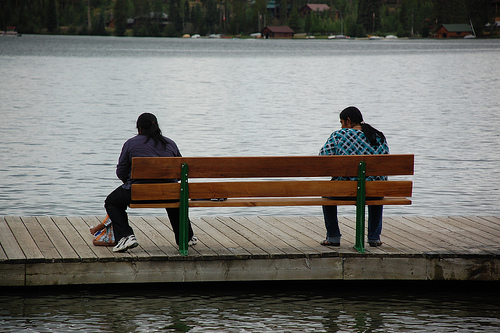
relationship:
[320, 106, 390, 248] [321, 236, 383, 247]
woman in sandals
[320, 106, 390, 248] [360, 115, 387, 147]
woman has pony tail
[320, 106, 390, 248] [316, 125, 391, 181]
woman in striped shirt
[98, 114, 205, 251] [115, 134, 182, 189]
person in shirt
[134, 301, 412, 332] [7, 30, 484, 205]
ripples in water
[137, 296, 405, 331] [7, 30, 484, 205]
reflections in water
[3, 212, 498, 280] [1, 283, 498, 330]
pier sitting water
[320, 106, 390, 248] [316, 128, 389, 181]
woman wearing checkered shirt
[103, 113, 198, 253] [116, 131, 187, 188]
woman wearing a shirt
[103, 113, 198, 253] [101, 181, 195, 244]
woman wearing black pants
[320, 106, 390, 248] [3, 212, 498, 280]
woman on a pier